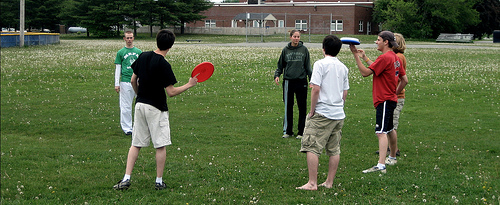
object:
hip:
[304, 112, 344, 132]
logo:
[285, 52, 306, 62]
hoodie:
[261, 40, 314, 81]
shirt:
[129, 50, 178, 112]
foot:
[112, 179, 132, 192]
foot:
[153, 182, 167, 190]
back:
[135, 51, 168, 106]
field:
[0, 52, 500, 205]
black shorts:
[375, 100, 397, 133]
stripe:
[0, 32, 59, 36]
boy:
[294, 35, 351, 191]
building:
[175, 0, 382, 35]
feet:
[293, 178, 335, 193]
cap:
[377, 30, 399, 48]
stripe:
[282, 80, 289, 136]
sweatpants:
[280, 79, 307, 136]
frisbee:
[190, 61, 215, 83]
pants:
[278, 78, 310, 135]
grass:
[0, 33, 500, 205]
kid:
[113, 28, 142, 134]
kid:
[374, 33, 405, 157]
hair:
[153, 28, 178, 51]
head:
[157, 29, 175, 52]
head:
[122, 30, 134, 45]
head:
[321, 35, 343, 57]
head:
[288, 29, 303, 44]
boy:
[349, 31, 409, 173]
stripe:
[378, 100, 386, 134]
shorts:
[373, 102, 396, 134]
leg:
[147, 121, 171, 190]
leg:
[113, 108, 151, 192]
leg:
[294, 117, 340, 191]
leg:
[320, 120, 342, 189]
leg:
[360, 103, 398, 174]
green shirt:
[114, 46, 142, 81]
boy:
[111, 29, 206, 190]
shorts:
[298, 109, 346, 156]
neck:
[156, 49, 169, 55]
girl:
[272, 30, 312, 138]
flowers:
[0, 39, 499, 205]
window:
[294, 20, 308, 31]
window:
[203, 19, 217, 30]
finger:
[193, 73, 201, 78]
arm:
[160, 60, 191, 97]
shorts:
[129, 101, 173, 149]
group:
[111, 30, 412, 192]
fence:
[1, 34, 61, 46]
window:
[330, 19, 344, 31]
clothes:
[274, 41, 312, 137]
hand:
[187, 72, 203, 86]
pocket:
[303, 120, 318, 132]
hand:
[306, 109, 315, 119]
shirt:
[308, 58, 350, 121]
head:
[374, 30, 399, 51]